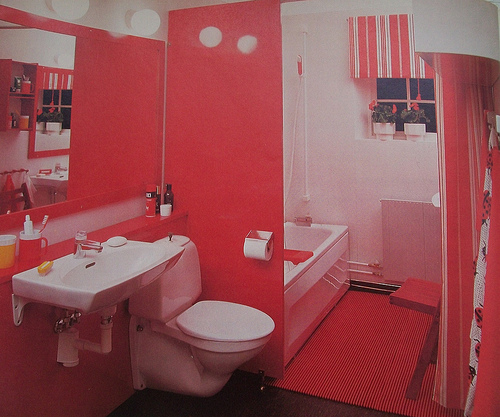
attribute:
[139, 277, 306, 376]
toilet — white, seat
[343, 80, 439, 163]
pot — flower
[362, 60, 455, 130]
window — background, shade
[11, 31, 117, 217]
mirror — bathroom, hanging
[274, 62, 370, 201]
wall — white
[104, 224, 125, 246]
soap — bar, white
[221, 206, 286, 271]
paper — toilet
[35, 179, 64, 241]
brush — tooth, scrub, pink, cleaning, red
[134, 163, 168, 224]
creme — shaving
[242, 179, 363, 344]
bathtub — white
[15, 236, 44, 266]
cup — plastic, holding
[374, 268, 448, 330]
rug — pink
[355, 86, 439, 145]
plant — small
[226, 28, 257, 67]
decor — white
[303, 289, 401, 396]
mat — red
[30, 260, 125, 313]
porcelain — white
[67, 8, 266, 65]
lighting — row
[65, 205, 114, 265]
faucet — silver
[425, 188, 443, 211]
knob — white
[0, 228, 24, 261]
container — yellow